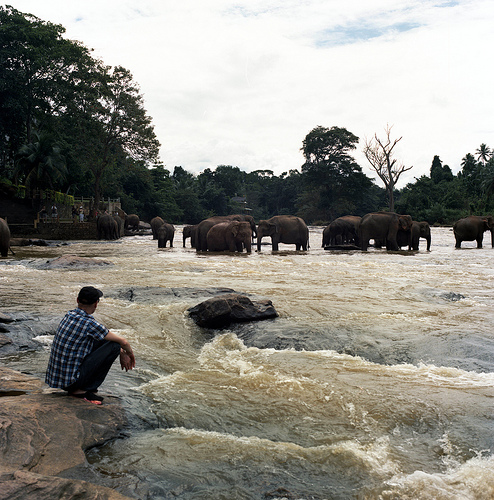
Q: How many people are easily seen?
A: One.